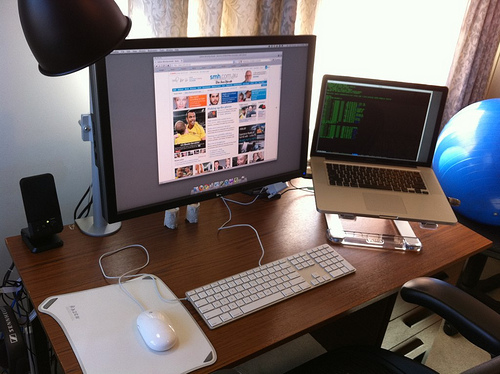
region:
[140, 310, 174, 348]
mouse on the mouse pad.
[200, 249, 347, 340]
keyboard on the desk.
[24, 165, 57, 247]
speaker on the desk.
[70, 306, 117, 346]
white mouse pad on the desk.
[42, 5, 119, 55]
black lamp above desk.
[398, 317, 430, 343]
drawer beneath the desk.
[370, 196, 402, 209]
mouse pad on laptop.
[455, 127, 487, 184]
big blue exercise ball.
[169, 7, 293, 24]
curtains behind the monitor.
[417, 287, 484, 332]
arm of the chair.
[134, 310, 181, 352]
The white mouse on the desk.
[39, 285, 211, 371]
The white mouse pad on the desk.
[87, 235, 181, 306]
The wire connected to the mouse.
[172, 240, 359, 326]
The white keyboard on the desk.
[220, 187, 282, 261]
The wire connected to the keyboard.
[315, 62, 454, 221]
The laptop on the desk.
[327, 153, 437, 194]
The black keyboard on the laptop.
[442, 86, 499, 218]
The blue ball on the right.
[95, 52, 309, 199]
The flat screen monitor.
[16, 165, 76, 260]
The black speaker to the left of the monitor screen.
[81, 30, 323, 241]
an hd computer monitor.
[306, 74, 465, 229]
an open laptop computer.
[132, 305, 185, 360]
a white computer mouse.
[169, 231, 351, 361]
a computer keyboard.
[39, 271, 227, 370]
a flat surface.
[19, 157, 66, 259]
a speaker on a computer desk.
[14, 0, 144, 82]
a light suspended over a desk.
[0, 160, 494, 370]
a computer desk.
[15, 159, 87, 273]
a speaker on top of a desk.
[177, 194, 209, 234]
a support under a monitor.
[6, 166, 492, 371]
dark wooden desk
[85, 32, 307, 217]
large flat screen monitor on desk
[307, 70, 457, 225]
laptop on stand above desk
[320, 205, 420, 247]
clear plastic stand holding laptop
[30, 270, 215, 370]
white mouse pad on desk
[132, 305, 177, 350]
white mouse on pad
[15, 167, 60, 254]
black speaker near monitor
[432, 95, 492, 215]
large blue ball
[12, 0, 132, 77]
black desk lamp above desk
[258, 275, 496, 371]
dark colored office chair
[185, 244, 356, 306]
A computer keyboard in the picture.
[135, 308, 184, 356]
A mouse on the table.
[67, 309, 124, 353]
A mouse pad in the picture.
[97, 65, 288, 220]
A monitor in the photo.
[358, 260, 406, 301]
A wooden table in the photo.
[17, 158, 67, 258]
A speaker on the table.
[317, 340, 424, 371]
A seat in the picture.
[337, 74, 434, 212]
A laptop in the photo.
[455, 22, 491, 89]
A curtain in the picture.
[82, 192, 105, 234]
A monitor stand in the photo.